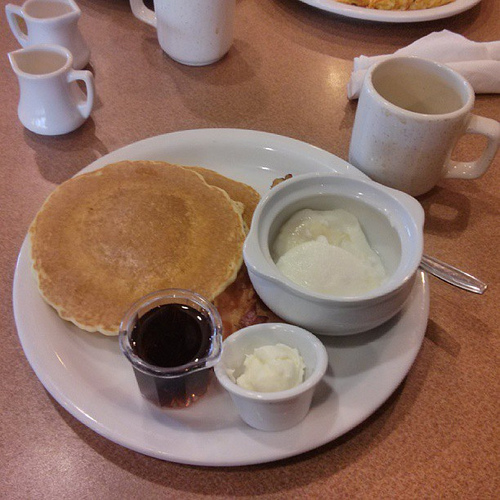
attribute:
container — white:
[218, 322, 328, 431]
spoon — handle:
[227, 160, 481, 300]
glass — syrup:
[113, 290, 225, 411]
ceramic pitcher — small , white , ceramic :
[0, 33, 105, 139]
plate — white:
[283, 0, 477, 40]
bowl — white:
[210, 319, 329, 429]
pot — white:
[236, 170, 434, 344]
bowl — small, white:
[254, 397, 285, 427]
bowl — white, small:
[160, 375, 196, 399]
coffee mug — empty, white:
[390, 118, 426, 158]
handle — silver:
[421, 258, 451, 278]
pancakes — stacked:
[25, 156, 263, 342]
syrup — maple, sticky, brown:
[114, 289, 224, 409]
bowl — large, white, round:
[237, 169, 430, 339]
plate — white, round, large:
[6, 123, 436, 476]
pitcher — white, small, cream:
[6, 39, 99, 145]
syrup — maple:
[132, 309, 212, 366]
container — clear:
[118, 286, 225, 410]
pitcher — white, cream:
[0, 1, 98, 70]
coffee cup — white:
[340, 52, 481, 201]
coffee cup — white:
[124, 0, 239, 76]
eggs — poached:
[263, 204, 391, 296]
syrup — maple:
[130, 302, 212, 366]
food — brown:
[23, 156, 244, 332]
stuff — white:
[232, 337, 306, 390]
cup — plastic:
[121, 291, 216, 412]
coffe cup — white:
[349, 55, 498, 195]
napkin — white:
[340, 25, 493, 105]